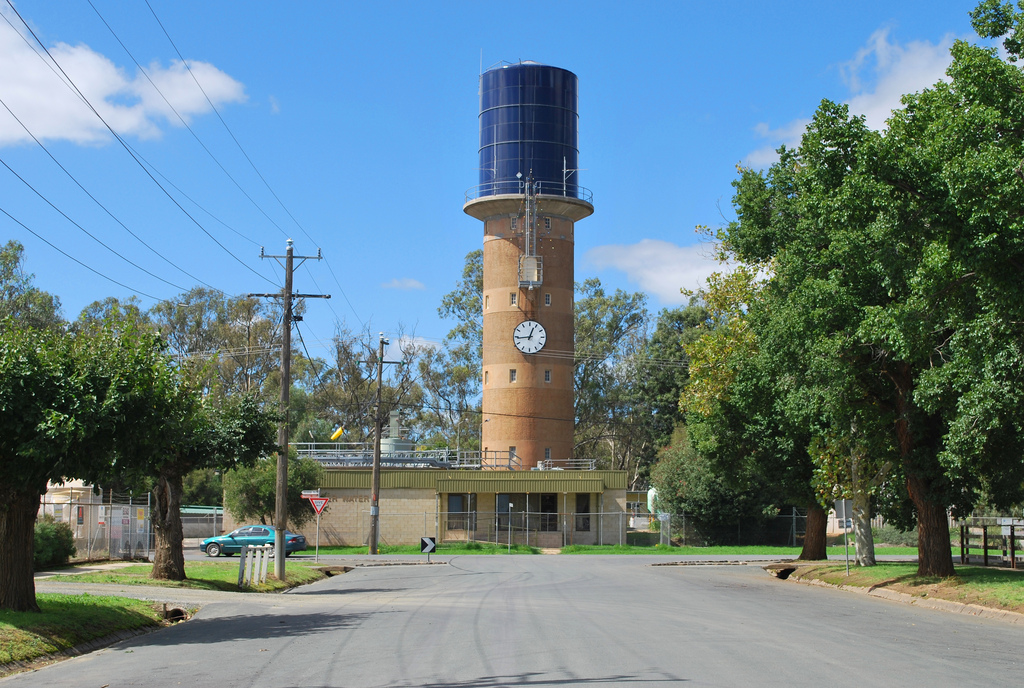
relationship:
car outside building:
[182, 509, 344, 566] [182, 461, 666, 566]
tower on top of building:
[467, 66, 597, 202] [215, 66, 650, 537]